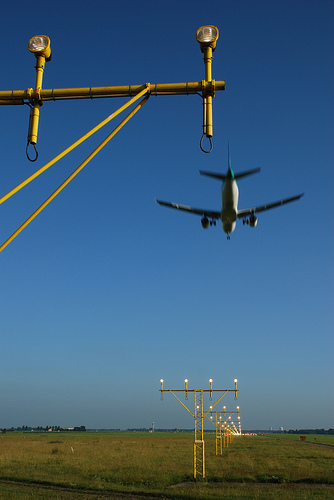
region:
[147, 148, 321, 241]
airplane coming in for a landing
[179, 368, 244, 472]
lights to light up the runway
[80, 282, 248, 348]
clear skies with no clouds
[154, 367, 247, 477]
yellow towers with lights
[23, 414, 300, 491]
large green field near runways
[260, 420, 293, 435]
water towers in the distance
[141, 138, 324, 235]
green and white airplane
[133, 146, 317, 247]
airplane with wheels down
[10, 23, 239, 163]
close up of lights on the runway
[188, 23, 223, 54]
light attached to yellow metal bars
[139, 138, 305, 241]
airplane in the sky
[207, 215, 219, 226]
airplane wheels let down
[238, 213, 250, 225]
airplane wheels let down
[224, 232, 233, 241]
front airplane wheels let down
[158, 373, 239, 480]
utility pole with four lights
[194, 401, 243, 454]
utlity pole with four lights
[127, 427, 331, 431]
row of trees in the backgroun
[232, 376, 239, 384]
light on the utility pole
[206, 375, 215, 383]
light on the utility pole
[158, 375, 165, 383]
light on the utility pole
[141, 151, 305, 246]
airplane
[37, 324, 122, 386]
white clouds in blue sky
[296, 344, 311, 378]
white clouds in blue sky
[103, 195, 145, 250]
white clouds in blue sky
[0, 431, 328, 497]
grassy field at airport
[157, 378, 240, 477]
row of lights at airport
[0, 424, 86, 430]
row of trees near airport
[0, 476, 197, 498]
path through airport field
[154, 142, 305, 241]
airplane approaching airport runway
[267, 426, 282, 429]
white structures at airport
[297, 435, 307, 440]
red sign in airport field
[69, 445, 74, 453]
white pole in airport field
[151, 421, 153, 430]
white tower at airport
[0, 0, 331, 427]
dark blue sky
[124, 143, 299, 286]
the plane is flying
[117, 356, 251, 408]
the lights are on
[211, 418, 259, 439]
red lights in the distance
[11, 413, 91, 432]
buildings in the background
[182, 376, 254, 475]
rows of lights in the distance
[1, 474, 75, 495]
the road is grey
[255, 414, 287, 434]
two structures in the distance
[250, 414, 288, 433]
the structures are white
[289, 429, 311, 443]
a red sign in the background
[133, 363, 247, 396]
four lights in a row